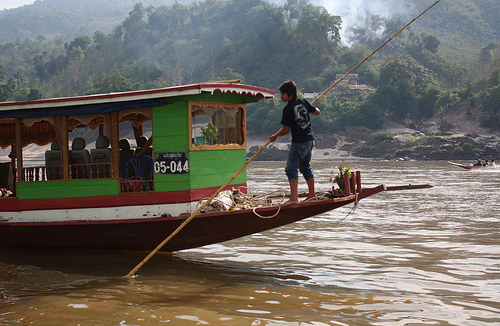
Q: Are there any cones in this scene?
A: No, there are no cones.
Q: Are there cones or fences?
A: No, there are no cones or fences.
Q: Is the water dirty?
A: Yes, the water is dirty.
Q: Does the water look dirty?
A: Yes, the water is dirty.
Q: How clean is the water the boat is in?
A: The water is dirty.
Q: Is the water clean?
A: No, the water is dirty.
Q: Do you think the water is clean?
A: No, the water is dirty.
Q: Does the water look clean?
A: No, the water is dirty.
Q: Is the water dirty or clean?
A: The water is dirty.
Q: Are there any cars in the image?
A: No, there are no cars.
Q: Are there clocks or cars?
A: No, there are no cars or clocks.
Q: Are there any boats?
A: Yes, there is a boat.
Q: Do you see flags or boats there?
A: Yes, there is a boat.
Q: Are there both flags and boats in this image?
A: No, there is a boat but no flags.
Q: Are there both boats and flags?
A: No, there is a boat but no flags.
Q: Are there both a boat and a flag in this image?
A: No, there is a boat but no flags.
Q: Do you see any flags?
A: No, there are no flags.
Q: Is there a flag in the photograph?
A: No, there are no flags.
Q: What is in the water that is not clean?
A: The boat is in the water.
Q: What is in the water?
A: The boat is in the water.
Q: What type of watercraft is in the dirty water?
A: The watercraft is a boat.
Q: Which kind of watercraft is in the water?
A: The watercraft is a boat.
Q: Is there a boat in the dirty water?
A: Yes, there is a boat in the water.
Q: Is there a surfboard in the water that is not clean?
A: No, there is a boat in the water.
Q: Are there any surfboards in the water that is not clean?
A: No, there is a boat in the water.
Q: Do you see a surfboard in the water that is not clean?
A: No, there is a boat in the water.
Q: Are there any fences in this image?
A: No, there are no fences.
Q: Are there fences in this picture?
A: No, there are no fences.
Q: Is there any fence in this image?
A: No, there are no fences.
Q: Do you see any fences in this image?
A: No, there are no fences.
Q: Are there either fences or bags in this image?
A: No, there are no fences or bags.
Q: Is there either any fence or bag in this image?
A: No, there are no fences or bags.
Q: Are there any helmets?
A: No, there are no helmets.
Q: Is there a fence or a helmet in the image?
A: No, there are no helmets or fences.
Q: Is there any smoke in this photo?
A: Yes, there is smoke.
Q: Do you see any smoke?
A: Yes, there is smoke.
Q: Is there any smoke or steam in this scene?
A: Yes, there is smoke.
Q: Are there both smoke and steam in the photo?
A: No, there is smoke but no steam.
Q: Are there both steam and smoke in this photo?
A: No, there is smoke but no steam.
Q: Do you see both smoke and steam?
A: No, there is smoke but no steam.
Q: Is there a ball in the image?
A: No, there are no balls.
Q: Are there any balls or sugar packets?
A: No, there are no balls or sugar packets.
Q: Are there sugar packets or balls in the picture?
A: No, there are no balls or sugar packets.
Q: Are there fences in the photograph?
A: No, there are no fences.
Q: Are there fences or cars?
A: No, there are no fences or cars.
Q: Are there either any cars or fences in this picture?
A: No, there are no fences or cars.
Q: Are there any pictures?
A: No, there are no pictures.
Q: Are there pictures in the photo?
A: No, there are no pictures.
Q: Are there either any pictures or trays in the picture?
A: No, there are no pictures or trays.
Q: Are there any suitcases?
A: No, there are no suitcases.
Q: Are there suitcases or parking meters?
A: No, there are no suitcases or parking meters.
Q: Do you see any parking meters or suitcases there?
A: No, there are no suitcases or parking meters.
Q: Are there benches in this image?
A: No, there are no benches.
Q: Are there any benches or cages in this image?
A: No, there are no benches or cages.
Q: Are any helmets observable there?
A: No, there are no helmets.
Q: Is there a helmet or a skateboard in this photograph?
A: No, there are no helmets or skateboards.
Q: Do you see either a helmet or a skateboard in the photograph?
A: No, there are no helmets or skateboards.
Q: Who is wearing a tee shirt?
A: The boy is wearing a tee shirt.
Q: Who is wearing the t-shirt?
A: The boy is wearing a tee shirt.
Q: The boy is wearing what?
A: The boy is wearing a t-shirt.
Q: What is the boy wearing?
A: The boy is wearing a t-shirt.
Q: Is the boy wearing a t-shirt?
A: Yes, the boy is wearing a t-shirt.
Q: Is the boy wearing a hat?
A: No, the boy is wearing a t-shirt.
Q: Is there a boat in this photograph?
A: Yes, there is a boat.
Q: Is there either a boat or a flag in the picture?
A: Yes, there is a boat.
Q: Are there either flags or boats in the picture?
A: Yes, there is a boat.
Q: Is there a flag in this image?
A: No, there are no flags.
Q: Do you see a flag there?
A: No, there are no flags.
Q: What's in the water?
A: The boat is in the water.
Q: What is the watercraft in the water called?
A: The watercraft is a boat.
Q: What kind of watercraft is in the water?
A: The watercraft is a boat.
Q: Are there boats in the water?
A: Yes, there is a boat in the water.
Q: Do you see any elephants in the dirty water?
A: No, there is a boat in the water.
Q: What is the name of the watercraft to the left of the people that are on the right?
A: The watercraft is a boat.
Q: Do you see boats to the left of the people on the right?
A: Yes, there is a boat to the left of the people.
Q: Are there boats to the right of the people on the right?
A: No, the boat is to the left of the people.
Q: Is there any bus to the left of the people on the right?
A: No, there is a boat to the left of the people.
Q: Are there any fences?
A: No, there are no fences.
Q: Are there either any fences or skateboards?
A: No, there are no fences or skateboards.